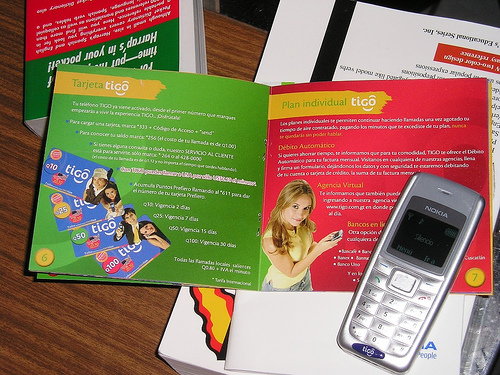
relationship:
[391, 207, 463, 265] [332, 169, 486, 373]
screen of phone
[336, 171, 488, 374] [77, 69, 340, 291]
phone on top of book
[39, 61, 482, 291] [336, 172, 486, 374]
tigo for cellphone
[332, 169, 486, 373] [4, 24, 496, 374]
phone on desk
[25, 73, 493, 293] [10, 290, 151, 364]
book on desk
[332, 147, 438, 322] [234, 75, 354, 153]
cellphone on papers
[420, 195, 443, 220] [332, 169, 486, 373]
nokia on phone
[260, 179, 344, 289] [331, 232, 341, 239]
woman with phone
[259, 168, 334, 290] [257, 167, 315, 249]
lady with hair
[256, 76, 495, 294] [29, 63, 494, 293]
page seven in book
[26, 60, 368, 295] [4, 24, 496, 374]
paper on desk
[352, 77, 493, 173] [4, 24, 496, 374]
paper on desk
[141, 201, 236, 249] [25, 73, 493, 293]
writing on book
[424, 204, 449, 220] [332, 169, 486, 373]
nokia on phone